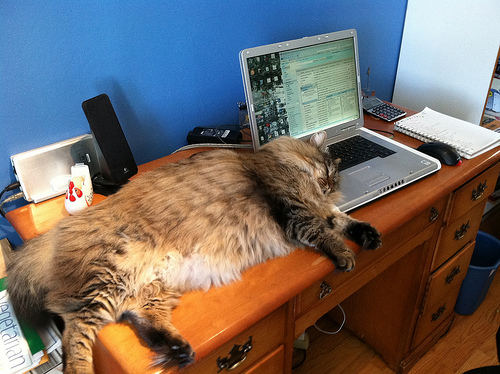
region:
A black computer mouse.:
[412, 140, 462, 167]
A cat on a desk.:
[2, 127, 379, 368]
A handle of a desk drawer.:
[210, 330, 255, 366]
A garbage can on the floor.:
[450, 226, 496, 312]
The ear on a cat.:
[306, 127, 326, 147]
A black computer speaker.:
[76, 90, 136, 180]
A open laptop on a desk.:
[235, 25, 440, 211]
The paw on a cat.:
[330, 215, 380, 250]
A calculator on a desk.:
[360, 91, 405, 121]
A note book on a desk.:
[391, 105, 497, 158]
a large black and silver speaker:
[82, 93, 144, 182]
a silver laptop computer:
[237, 25, 444, 217]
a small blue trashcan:
[456, 228, 498, 322]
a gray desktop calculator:
[358, 93, 405, 123]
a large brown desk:
[7, 103, 499, 373]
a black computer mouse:
[417, 137, 459, 167]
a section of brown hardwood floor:
[304, 325, 391, 372]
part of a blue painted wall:
[5, 0, 193, 85]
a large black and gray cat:
[0, 126, 385, 371]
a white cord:
[314, 303, 349, 341]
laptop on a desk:
[221, 34, 442, 212]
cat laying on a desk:
[8, 131, 393, 366]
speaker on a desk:
[74, 85, 133, 202]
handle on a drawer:
[203, 333, 267, 373]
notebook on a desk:
[389, 89, 498, 172]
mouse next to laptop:
[406, 137, 468, 171]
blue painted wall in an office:
[46, 7, 242, 99]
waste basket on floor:
[471, 223, 498, 325]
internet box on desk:
[8, 133, 105, 200]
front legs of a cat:
[291, 215, 386, 279]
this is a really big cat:
[4, 131, 387, 372]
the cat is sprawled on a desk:
[3, 132, 388, 372]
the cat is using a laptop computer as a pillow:
[236, 22, 442, 214]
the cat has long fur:
[4, 126, 386, 371]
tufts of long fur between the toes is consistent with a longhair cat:
[143, 335, 200, 372]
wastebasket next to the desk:
[449, 225, 498, 320]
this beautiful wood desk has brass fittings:
[6, 91, 498, 372]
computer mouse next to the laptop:
[413, 135, 465, 170]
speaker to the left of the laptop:
[76, 87, 141, 197]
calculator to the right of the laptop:
[361, 93, 408, 123]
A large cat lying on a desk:
[6, 24, 496, 369]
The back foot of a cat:
[130, 308, 199, 372]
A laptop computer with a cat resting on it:
[234, 23, 444, 226]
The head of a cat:
[277, 128, 348, 203]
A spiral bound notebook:
[389, 103, 499, 163]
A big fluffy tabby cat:
[3, 124, 385, 371]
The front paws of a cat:
[323, 214, 387, 278]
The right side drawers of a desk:
[407, 159, 496, 356]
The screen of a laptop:
[239, 28, 366, 147]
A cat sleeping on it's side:
[8, 126, 386, 372]